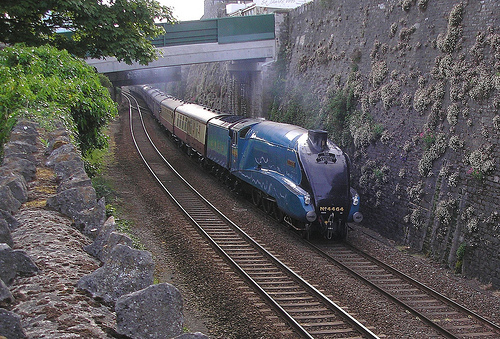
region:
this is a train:
[110, 36, 429, 281]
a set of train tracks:
[111, 95, 275, 312]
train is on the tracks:
[123, 64, 490, 329]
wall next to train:
[259, 0, 499, 262]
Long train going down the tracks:
[114, 60, 381, 269]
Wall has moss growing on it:
[288, 18, 466, 228]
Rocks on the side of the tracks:
[18, 75, 173, 334]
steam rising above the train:
[268, 68, 338, 145]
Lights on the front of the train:
[281, 190, 375, 239]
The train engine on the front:
[228, 99, 364, 250]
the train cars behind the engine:
[127, 77, 243, 164]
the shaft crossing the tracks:
[45, 5, 302, 75]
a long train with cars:
[135, 68, 372, 250]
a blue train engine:
[207, 110, 364, 245]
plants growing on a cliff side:
[362, 20, 490, 142]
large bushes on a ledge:
[0, 0, 172, 150]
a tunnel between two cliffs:
[23, 13, 297, 77]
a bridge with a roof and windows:
[17, 0, 307, 80]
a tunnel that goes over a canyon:
[6, 5, 311, 112]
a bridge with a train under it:
[27, 11, 371, 255]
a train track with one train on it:
[126, 88, 486, 335]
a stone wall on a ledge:
[0, 90, 191, 337]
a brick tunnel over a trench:
[35, 8, 307, 92]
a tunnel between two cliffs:
[29, 1, 311, 102]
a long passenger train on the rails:
[132, 74, 399, 244]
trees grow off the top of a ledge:
[0, 0, 170, 165]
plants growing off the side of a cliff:
[349, 10, 499, 160]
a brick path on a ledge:
[2, 88, 180, 322]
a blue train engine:
[216, 108, 366, 253]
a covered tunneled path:
[46, 5, 297, 83]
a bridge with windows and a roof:
[32, 5, 306, 95]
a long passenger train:
[133, 75, 367, 250]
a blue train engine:
[216, 114, 366, 248]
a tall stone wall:
[3, 88, 185, 336]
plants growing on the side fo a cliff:
[327, 10, 492, 188]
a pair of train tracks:
[126, 87, 486, 337]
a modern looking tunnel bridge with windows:
[35, 4, 286, 71]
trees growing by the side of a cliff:
[0, 0, 173, 163]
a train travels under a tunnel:
[115, 7, 402, 234]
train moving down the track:
[126, 79, 368, 246]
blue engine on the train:
[226, 113, 369, 245]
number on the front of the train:
[316, 203, 345, 215]